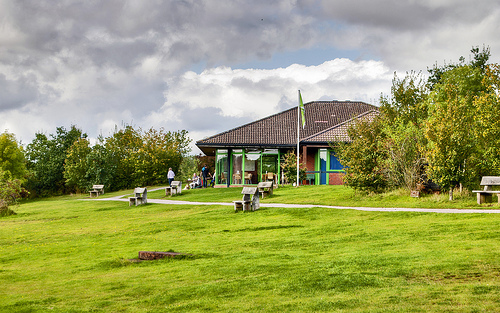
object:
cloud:
[0, 0, 497, 158]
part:
[168, 25, 247, 63]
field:
[1, 42, 500, 313]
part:
[227, 236, 272, 261]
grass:
[0, 183, 497, 313]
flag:
[300, 93, 306, 130]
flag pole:
[296, 90, 301, 186]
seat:
[129, 187, 147, 207]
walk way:
[77, 198, 500, 215]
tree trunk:
[447, 185, 454, 200]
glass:
[245, 154, 261, 185]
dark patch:
[230, 225, 300, 231]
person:
[166, 167, 175, 187]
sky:
[1, 0, 498, 154]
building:
[195, 100, 396, 188]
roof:
[196, 100, 382, 144]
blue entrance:
[314, 149, 330, 186]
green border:
[314, 148, 330, 185]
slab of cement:
[138, 250, 187, 259]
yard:
[1, 170, 497, 313]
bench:
[472, 175, 500, 204]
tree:
[468, 61, 500, 185]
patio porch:
[215, 149, 281, 186]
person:
[199, 164, 212, 188]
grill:
[211, 174, 216, 188]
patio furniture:
[244, 172, 253, 185]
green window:
[215, 149, 231, 185]